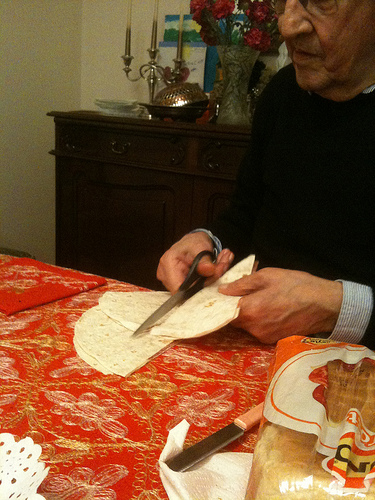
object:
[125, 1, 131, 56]
candlestick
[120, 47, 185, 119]
candlestick holder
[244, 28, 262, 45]
flowers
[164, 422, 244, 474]
blade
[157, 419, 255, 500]
napkin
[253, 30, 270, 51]
flowers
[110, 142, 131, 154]
handle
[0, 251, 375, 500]
table cloth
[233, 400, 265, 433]
handle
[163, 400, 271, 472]
knife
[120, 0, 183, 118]
candleabra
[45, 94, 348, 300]
chest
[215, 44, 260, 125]
vase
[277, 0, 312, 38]
man's nose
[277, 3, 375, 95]
face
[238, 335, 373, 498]
bread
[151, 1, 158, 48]
candle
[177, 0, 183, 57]
candle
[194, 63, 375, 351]
shirt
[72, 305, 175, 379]
tortillas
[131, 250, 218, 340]
scissors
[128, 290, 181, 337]
blade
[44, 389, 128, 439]
design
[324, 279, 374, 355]
cuff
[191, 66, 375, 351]
sweater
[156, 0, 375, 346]
man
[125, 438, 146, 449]
stitching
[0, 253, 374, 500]
table